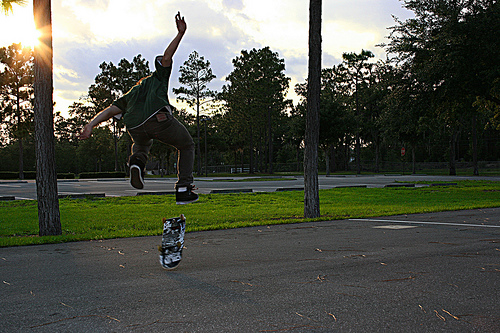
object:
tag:
[155, 113, 168, 123]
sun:
[12, 18, 56, 54]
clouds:
[44, 1, 161, 52]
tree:
[173, 49, 224, 173]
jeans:
[127, 112, 195, 188]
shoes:
[129, 159, 145, 190]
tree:
[224, 46, 293, 175]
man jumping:
[46, 3, 265, 255]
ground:
[324, 171, 453, 198]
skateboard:
[157, 213, 187, 270]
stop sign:
[401, 146, 406, 155]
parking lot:
[2, 172, 483, 198]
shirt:
[112, 55, 176, 130]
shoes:
[174, 184, 199, 204]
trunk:
[32, 0, 58, 236]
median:
[1, 177, 498, 246]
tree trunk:
[304, 0, 321, 219]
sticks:
[440, 308, 459, 320]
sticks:
[433, 309, 446, 322]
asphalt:
[375, 238, 489, 316]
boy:
[77, 11, 201, 205]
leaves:
[241, 51, 255, 61]